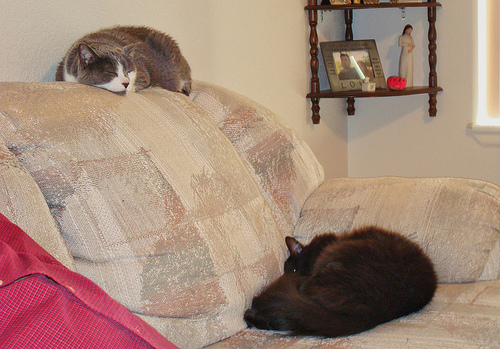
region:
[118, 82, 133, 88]
Cat has black nose.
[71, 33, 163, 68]
Cat has gray ears.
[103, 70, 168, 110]
Cat has white cheeks.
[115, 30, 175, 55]
Cat has gray fur on back.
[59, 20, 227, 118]
Cat is laying on back top of couch.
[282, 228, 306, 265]
Cat has black ear.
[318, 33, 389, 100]
Picture frame on shelf.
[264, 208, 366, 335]
Cat is laying on couch.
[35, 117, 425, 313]
Couch is light colored.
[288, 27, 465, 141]
Wood shelf in corner of room.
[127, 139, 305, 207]
tand and gray pattern on sofa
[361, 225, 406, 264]
fur on brown cat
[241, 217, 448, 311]
brown cat curled up on sofa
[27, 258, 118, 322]
pink material on sofa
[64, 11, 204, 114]
gray cat on top of sofa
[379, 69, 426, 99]
pink ashtray on shelf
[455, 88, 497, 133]
edge of the window sill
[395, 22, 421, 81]
white statue on the shelf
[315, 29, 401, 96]
gray frame with picture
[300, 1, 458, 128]
brown shelf on the wall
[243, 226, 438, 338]
a curled up black cat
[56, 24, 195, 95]
a sleeping brown and white cat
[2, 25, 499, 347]
two cats sleeping on a couch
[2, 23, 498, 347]
a couch with two cats on it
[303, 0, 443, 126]
a wooden wall shelf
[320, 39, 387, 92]
a framed photo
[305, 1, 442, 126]
a corner wall shelf with framed photo on it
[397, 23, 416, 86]
a figurine in a white dress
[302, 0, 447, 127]
a wall shelf with a figurine on it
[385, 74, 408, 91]
a red object on the corner wall shelf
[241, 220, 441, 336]
a black cat on the couch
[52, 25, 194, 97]
a cat laying on top of the couch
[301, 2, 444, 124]
a brown shelf in the corner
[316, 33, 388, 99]
a picture frame on the shelf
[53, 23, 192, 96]
the cat is gray and white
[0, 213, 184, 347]
a red shirt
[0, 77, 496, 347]
the couch is a light brown color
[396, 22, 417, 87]
a figurine on the shelf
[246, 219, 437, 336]
the cat is curled up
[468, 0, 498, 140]
a window beside the shelf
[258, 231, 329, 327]
black cat on sofa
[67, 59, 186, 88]
gray and white cat on sofa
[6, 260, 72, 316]
red blanket on sofa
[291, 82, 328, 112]
brown shelf on wall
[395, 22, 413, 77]
cute statue on shelf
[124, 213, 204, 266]
tan and cream sofa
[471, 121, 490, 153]
white window sill on wall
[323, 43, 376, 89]
picture in frame on shelf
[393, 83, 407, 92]
red knick knack on shelf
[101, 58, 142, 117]
cat has closed eyes